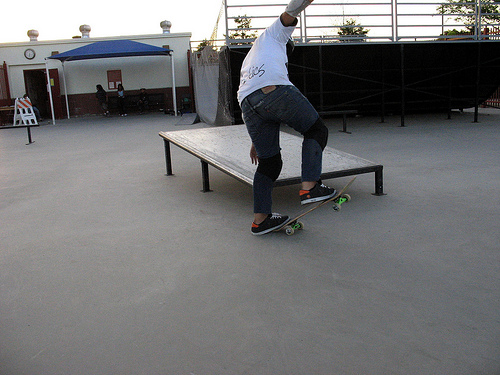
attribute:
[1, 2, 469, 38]
sky — cloudy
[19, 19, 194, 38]
vents — silver, aluminum, exhaust vents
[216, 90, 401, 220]
jeans — blue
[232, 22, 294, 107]
white shirt — short-sleeved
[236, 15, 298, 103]
shirt — white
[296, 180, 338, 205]
sneaker — black, white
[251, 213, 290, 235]
sneaker — black, white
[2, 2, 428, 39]
sky — daytime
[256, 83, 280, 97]
leather patch — brown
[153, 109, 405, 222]
wooden surface — short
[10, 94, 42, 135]
sign — warning 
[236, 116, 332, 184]
kneepads — black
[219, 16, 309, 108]
shirt — white, short-sleeved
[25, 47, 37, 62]
clock — round, outdoor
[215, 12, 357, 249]
man — skating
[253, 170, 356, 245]
skateboard — tilted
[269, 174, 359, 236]
skateboard — lifted, angled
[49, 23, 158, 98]
tent — blue, awning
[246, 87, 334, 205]
jeans — skinny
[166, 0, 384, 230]
man — unbalanced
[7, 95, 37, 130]
sign — safety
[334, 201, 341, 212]
green wheel — neon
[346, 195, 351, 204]
green wheel — neon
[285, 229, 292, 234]
green wheel — neon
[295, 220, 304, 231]
green wheel — neon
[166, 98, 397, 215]
ramp — wooden 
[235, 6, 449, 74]
fence — metal, elevated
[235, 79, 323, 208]
pants — black